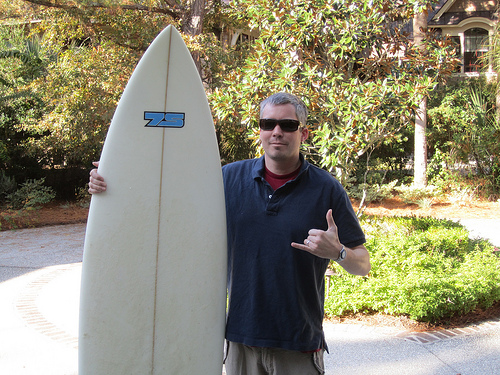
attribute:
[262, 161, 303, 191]
undershirt — burgundy, dark red, red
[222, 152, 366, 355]
shirt — blue, dark blue, polo style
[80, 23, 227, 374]
surfboard — white, large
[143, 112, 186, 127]
sticker — 75, blue, logo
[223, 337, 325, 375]
pants — beige, khaki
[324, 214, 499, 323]
bush — small, green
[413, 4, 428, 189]
tree trunk — tall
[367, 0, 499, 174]
building — house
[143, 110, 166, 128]
seven — blue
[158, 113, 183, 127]
s — blue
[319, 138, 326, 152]
leaf — green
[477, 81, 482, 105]
leaf — green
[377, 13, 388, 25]
leaf — green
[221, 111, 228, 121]
leaf — green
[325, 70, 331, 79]
leaf — green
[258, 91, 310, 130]
hair — gray